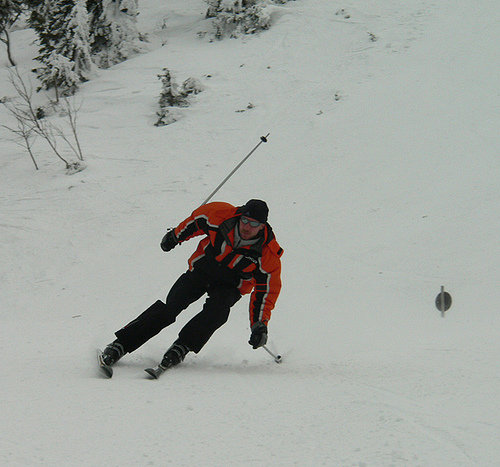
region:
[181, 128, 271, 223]
a man holding a ski pole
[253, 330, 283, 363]
a man holding a ski pole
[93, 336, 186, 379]
two black skis in the snow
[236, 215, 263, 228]
a man with sunglasses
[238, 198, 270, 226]
a man with a black hat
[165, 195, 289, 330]
a man with a red and black jacket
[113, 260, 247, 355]
a man with black pants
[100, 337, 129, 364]
a man with black boots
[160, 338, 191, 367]
a man with black boots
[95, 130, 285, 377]
a man riding with skis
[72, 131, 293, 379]
Man skiing down the hill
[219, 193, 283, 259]
Man wearing a skull cap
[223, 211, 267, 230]
Man wearing sunglasses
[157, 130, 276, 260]
Man holding ski poles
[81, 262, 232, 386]
Man wearing shin protection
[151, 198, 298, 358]
skier wearing red black and white jacket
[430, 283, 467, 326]
Marker in the snow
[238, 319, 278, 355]
Man with gloves on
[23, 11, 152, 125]
Heavy snow covering trees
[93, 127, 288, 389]
Skier banking to the left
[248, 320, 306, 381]
A ski pole in the man hand.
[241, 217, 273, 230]
The person is wearing goggles.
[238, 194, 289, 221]
The man is wearing a cap.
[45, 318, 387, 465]
The ground is covered in snow.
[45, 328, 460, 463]
The snow is white.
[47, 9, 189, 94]
The trees is covered in snow.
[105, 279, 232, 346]
The man pants is black.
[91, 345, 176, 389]
The man is wearing skis.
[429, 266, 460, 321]
A small sign in the snow.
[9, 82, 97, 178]
The small tree has no leaves.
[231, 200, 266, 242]
The man has shades on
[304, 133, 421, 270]
The snow is white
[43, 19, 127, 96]
The tree is covered in snow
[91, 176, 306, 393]
The man is skiing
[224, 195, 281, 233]
The man has a hat on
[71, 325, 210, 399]
The skis are in the snow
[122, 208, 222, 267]
The man has gloves on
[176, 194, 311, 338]
The jacket is orange and black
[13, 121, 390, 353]
The man has ski poles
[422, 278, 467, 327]
An object is in the snow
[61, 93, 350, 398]
man skiing down a slope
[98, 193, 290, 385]
man is leaning to the right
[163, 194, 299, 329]
orange, black, and white jacket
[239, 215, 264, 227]
glasses on the face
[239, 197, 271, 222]
cap on the head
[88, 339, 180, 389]
a pair of skis on the feet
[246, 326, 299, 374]
ski pole sticking in the snow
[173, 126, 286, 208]
ski pole in the air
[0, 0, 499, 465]
white snow on the ground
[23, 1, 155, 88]
trees covered in snow